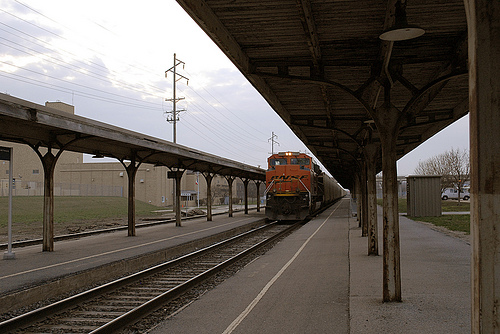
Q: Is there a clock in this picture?
A: No, there are no clocks.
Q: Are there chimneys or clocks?
A: No, there are no clocks or chimneys.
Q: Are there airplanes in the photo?
A: No, there are no airplanes.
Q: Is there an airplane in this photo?
A: No, there are no airplanes.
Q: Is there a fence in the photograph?
A: Yes, there is a fence.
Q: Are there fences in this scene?
A: Yes, there is a fence.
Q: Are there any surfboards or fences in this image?
A: Yes, there is a fence.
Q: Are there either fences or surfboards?
A: Yes, there is a fence.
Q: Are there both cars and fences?
A: Yes, there are both a fence and a car.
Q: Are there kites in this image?
A: No, there are no kites.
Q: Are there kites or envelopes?
A: No, there are no kites or envelopes.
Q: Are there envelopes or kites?
A: No, there are no kites or envelopes.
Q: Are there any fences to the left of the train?
A: Yes, there is a fence to the left of the train.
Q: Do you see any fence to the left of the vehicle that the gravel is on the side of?
A: Yes, there is a fence to the left of the train.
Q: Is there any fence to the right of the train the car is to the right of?
A: No, the fence is to the left of the train.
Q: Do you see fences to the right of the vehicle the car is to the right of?
A: No, the fence is to the left of the train.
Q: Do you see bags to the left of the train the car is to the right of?
A: No, there is a fence to the left of the train.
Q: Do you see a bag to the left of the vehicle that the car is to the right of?
A: No, there is a fence to the left of the train.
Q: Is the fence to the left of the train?
A: Yes, the fence is to the left of the train.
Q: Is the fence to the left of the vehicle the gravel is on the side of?
A: Yes, the fence is to the left of the train.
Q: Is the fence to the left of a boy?
A: No, the fence is to the left of the train.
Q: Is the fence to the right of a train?
A: No, the fence is to the left of a train.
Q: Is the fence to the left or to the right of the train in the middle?
A: The fence is to the left of the train.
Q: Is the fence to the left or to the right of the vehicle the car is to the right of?
A: The fence is to the left of the train.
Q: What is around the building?
A: The fence is around the building.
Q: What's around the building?
A: The fence is around the building.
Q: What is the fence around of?
A: The fence is around the building.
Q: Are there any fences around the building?
A: Yes, there is a fence around the building.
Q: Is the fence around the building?
A: Yes, the fence is around the building.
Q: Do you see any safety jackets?
A: No, there are no safety jackets.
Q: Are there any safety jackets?
A: No, there are no safety jackets.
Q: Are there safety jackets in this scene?
A: No, there are no safety jackets.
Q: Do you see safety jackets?
A: No, there are no safety jackets.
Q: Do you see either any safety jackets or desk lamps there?
A: No, there are no safety jackets or desk lamps.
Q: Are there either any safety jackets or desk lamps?
A: No, there are no safety jackets or desk lamps.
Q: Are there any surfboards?
A: No, there are no surfboards.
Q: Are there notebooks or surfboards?
A: No, there are no surfboards or notebooks.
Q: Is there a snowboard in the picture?
A: No, there are no snowboards.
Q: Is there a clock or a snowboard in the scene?
A: No, there are no snowboards or clocks.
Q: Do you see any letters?
A: Yes, there are letters.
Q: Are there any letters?
A: Yes, there are letters.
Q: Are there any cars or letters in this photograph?
A: Yes, there are letters.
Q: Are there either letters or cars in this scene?
A: Yes, there are letters.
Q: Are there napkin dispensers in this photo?
A: No, there are no napkin dispensers.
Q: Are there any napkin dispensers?
A: No, there are no napkin dispensers.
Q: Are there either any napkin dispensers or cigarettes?
A: No, there are no napkin dispensers or cigarettes.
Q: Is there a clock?
A: No, there are no clocks.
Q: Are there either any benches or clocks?
A: No, there are no clocks or benches.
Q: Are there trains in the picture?
A: Yes, there is a train.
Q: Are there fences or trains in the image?
A: Yes, there is a train.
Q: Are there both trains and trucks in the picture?
A: No, there is a train but no trucks.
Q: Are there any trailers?
A: No, there are no trailers.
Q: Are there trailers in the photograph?
A: No, there are no trailers.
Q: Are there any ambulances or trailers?
A: No, there are no trailers or ambulances.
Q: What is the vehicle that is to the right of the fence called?
A: The vehicle is a train.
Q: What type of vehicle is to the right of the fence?
A: The vehicle is a train.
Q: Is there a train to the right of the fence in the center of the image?
A: Yes, there is a train to the right of the fence.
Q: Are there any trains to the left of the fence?
A: No, the train is to the right of the fence.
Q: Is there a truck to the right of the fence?
A: No, there is a train to the right of the fence.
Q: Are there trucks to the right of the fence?
A: No, there is a train to the right of the fence.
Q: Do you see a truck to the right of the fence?
A: No, there is a train to the right of the fence.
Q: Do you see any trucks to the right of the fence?
A: No, there is a train to the right of the fence.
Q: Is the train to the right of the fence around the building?
A: Yes, the train is to the right of the fence.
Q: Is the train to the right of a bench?
A: No, the train is to the right of the fence.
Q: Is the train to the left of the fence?
A: No, the train is to the right of the fence.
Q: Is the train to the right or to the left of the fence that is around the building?
A: The train is to the right of the fence.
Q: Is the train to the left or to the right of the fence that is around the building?
A: The train is to the right of the fence.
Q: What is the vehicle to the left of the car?
A: The vehicle is a train.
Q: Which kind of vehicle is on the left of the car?
A: The vehicle is a train.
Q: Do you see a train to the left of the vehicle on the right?
A: Yes, there is a train to the left of the car.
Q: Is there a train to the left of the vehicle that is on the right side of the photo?
A: Yes, there is a train to the left of the car.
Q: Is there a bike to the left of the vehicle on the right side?
A: No, there is a train to the left of the car.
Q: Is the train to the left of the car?
A: Yes, the train is to the left of the car.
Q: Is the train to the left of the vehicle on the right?
A: Yes, the train is to the left of the car.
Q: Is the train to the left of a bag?
A: No, the train is to the left of the car.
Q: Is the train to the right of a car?
A: No, the train is to the left of a car.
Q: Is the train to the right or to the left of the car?
A: The train is to the left of the car.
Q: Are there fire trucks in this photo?
A: No, there are no fire trucks.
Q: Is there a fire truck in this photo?
A: No, there are no fire trucks.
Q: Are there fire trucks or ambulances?
A: No, there are no fire trucks or ambulances.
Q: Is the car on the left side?
A: No, the car is on the right of the image.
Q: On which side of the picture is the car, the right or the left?
A: The car is on the right of the image.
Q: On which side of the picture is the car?
A: The car is on the right of the image.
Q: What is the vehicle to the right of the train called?
A: The vehicle is a car.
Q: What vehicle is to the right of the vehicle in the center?
A: The vehicle is a car.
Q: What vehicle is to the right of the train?
A: The vehicle is a car.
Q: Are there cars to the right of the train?
A: Yes, there is a car to the right of the train.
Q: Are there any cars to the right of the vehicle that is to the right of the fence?
A: Yes, there is a car to the right of the train.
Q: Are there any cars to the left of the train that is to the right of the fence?
A: No, the car is to the right of the train.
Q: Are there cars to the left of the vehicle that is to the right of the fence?
A: No, the car is to the right of the train.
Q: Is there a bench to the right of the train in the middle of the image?
A: No, there is a car to the right of the train.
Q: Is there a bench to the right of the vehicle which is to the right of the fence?
A: No, there is a car to the right of the train.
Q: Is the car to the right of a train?
A: Yes, the car is to the right of a train.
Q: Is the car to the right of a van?
A: No, the car is to the right of a train.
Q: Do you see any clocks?
A: No, there are no clocks.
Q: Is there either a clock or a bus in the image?
A: No, there are no clocks or buses.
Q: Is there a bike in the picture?
A: No, there are no bikes.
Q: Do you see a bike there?
A: No, there are no bikes.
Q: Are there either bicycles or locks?
A: No, there are no bicycles or locks.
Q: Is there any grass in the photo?
A: Yes, there is grass.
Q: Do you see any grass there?
A: Yes, there is grass.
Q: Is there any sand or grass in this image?
A: Yes, there is grass.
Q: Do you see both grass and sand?
A: No, there is grass but no sand.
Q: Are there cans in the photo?
A: No, there are no cans.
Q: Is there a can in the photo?
A: No, there are no cans.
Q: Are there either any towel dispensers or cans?
A: No, there are no cans or towel dispensers.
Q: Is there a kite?
A: No, there are no kites.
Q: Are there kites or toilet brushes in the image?
A: No, there are no kites or toilet brushes.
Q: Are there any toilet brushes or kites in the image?
A: No, there are no kites or toilet brushes.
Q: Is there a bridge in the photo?
A: Yes, there is a bridge.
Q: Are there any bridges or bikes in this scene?
A: Yes, there is a bridge.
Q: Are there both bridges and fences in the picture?
A: Yes, there are both a bridge and a fence.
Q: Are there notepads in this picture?
A: No, there are no notepads.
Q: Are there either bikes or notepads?
A: No, there are no notepads or bikes.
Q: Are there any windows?
A: Yes, there is a window.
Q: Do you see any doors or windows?
A: Yes, there is a window.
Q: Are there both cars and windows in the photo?
A: Yes, there are both a window and a car.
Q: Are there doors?
A: No, there are no doors.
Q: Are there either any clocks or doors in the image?
A: No, there are no doors or clocks.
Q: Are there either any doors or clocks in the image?
A: No, there are no doors or clocks.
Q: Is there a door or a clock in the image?
A: No, there are no doors or clocks.